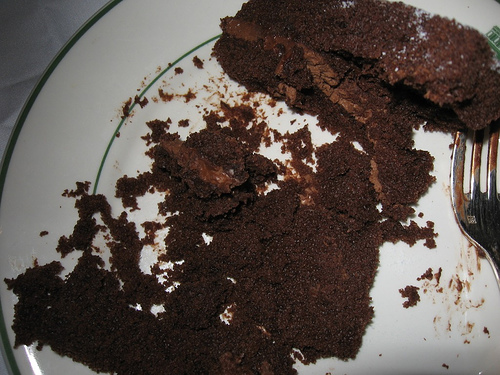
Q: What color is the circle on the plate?
A: Green.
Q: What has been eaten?
A: Chocolate cake.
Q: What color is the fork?
A: Silver.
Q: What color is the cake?
A: Brown.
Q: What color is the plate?
A: White.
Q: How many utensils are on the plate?
A: 1.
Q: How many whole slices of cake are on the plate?
A: 0.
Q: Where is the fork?
A: On the plate.